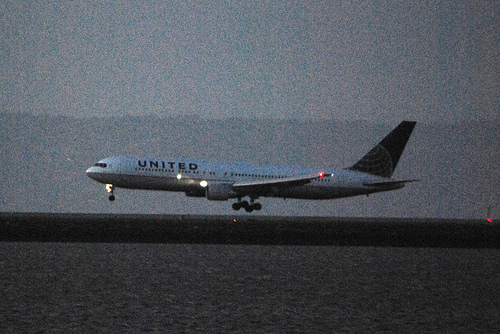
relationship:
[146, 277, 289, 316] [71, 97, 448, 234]
water underneath plane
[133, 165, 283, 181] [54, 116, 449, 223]
windows of plane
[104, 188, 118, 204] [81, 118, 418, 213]
wheels of plane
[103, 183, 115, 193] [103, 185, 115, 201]
light near landing gear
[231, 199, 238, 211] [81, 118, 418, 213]
wheel of plane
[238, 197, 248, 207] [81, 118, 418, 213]
wheel of plane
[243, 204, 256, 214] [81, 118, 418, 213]
wheel of plane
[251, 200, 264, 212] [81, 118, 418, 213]
wheel of plane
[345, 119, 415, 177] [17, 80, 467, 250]
tail wing of plane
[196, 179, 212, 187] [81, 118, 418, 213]
light working in plane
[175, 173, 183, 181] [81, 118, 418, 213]
light working in plane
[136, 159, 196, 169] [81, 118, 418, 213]
united on plane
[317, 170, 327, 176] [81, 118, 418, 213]
red light on plane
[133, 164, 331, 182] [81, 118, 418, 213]
windows on side of plane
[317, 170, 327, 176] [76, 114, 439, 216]
red light on plane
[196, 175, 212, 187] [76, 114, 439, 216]
light on plane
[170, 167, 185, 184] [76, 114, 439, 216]
light on plane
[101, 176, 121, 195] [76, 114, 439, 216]
light on plane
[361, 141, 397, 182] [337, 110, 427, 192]
logo on wings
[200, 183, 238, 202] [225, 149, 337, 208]
engine on wings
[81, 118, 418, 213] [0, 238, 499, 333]
plane flying above water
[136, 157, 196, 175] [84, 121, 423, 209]
united on body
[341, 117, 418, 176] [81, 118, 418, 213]
part on plane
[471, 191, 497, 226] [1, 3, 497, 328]
tower on picture